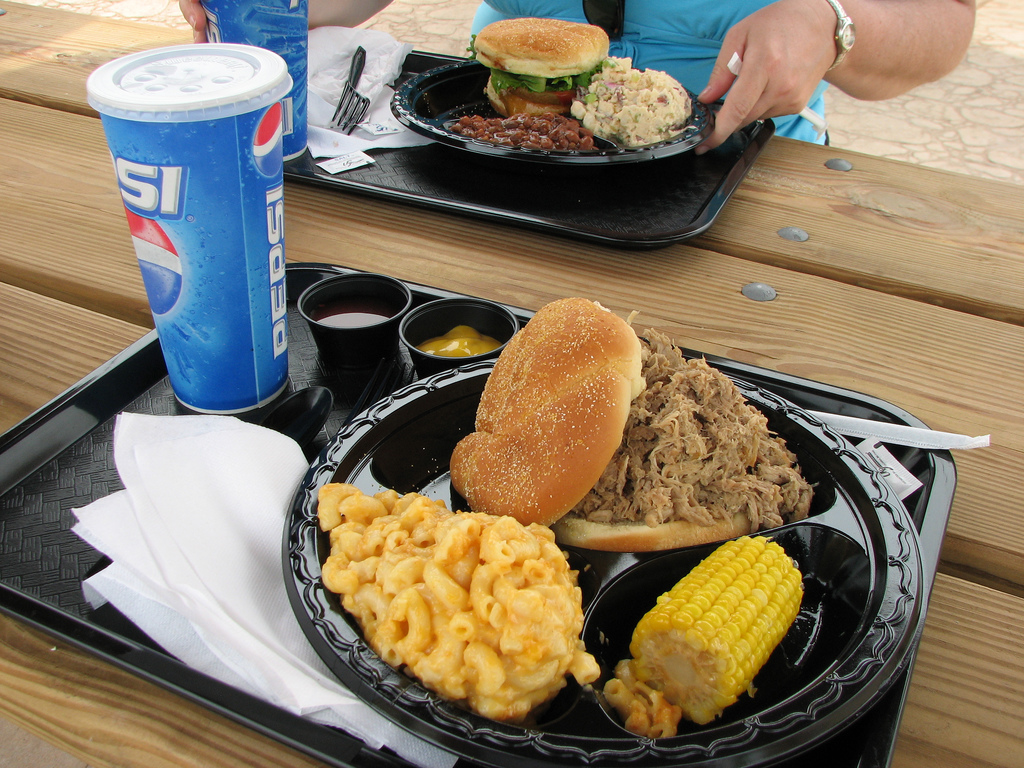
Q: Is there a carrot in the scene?
A: No, there are no carrots.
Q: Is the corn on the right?
A: Yes, the corn is on the right of the image.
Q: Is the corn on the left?
A: No, the corn is on the right of the image.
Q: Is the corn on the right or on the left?
A: The corn is on the right of the image.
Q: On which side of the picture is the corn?
A: The corn is on the right of the image.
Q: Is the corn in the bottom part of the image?
A: Yes, the corn is in the bottom of the image.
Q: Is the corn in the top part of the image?
A: No, the corn is in the bottom of the image.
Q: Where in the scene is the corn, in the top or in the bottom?
A: The corn is in the bottom of the image.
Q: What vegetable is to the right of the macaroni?
A: The vegetable is corn.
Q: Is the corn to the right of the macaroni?
A: Yes, the corn is to the right of the macaroni.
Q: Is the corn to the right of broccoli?
A: No, the corn is to the right of the macaroni.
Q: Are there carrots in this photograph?
A: No, there are no carrots.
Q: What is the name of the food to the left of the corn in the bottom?
A: The food is macaroni.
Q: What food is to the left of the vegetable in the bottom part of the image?
A: The food is macaroni.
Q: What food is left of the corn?
A: The food is macaroni.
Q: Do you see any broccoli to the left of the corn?
A: No, there is macaroni to the left of the corn.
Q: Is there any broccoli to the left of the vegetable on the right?
A: No, there is macaroni to the left of the corn.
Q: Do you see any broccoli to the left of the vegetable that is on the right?
A: No, there is macaroni to the left of the corn.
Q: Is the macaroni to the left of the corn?
A: Yes, the macaroni is to the left of the corn.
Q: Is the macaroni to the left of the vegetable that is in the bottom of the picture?
A: Yes, the macaroni is to the left of the corn.